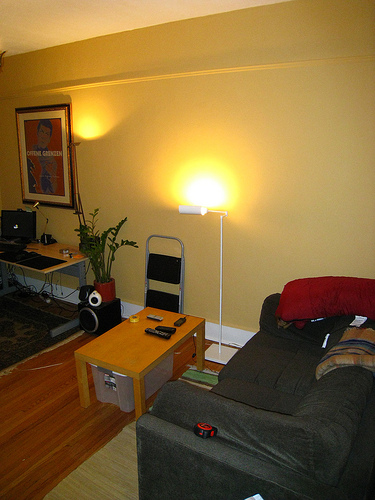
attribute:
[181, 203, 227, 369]
lamp — white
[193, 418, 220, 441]
tape measure — red, black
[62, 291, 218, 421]
table — light brown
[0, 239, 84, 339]
desk — light brown, wooden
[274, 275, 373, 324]
blanket — red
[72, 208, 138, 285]
plant — green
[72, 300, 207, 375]
table — light brown, wooden, coffee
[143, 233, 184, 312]
ladder — folded up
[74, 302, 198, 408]
wood — brown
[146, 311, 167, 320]
remote — grey